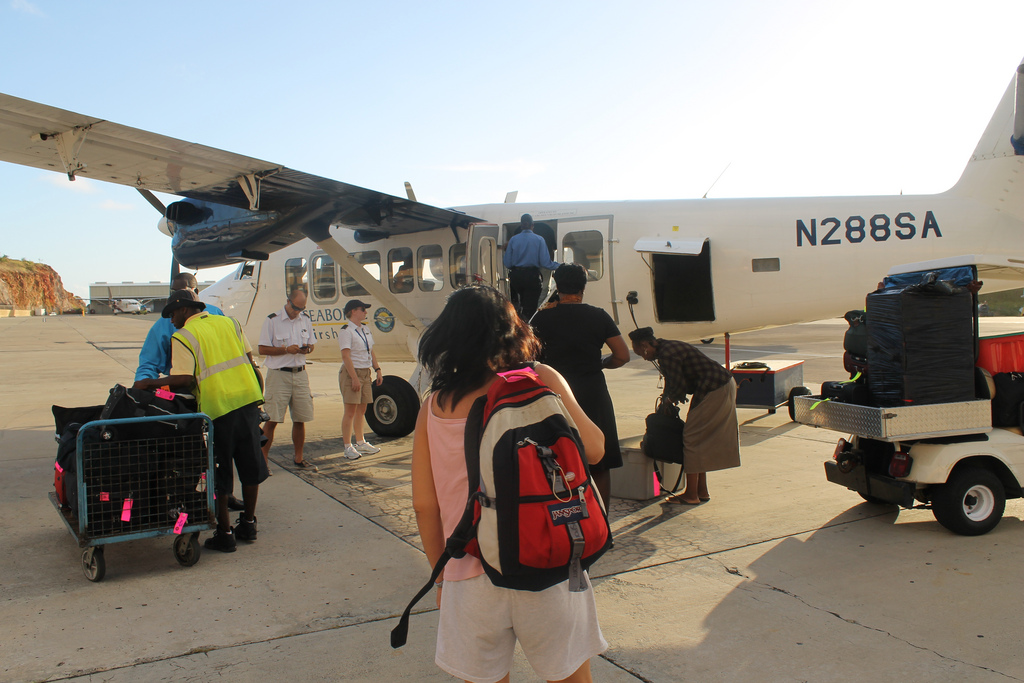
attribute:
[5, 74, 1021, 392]
plane — small, passenger